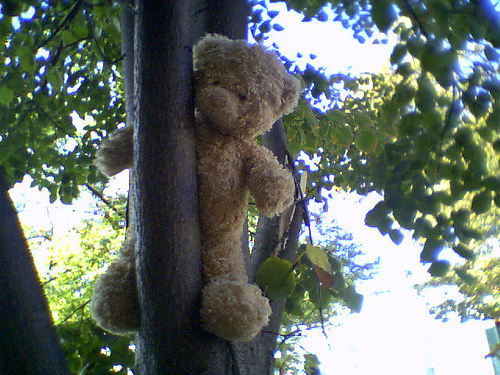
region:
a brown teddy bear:
[91, 29, 298, 339]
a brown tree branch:
[132, 1, 203, 354]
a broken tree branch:
[252, 131, 309, 373]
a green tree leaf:
[252, 255, 295, 300]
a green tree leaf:
[303, 245, 335, 275]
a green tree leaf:
[303, 352, 321, 369]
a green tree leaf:
[385, 227, 405, 243]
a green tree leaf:
[375, 215, 393, 235]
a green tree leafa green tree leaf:
[411, 215, 431, 241]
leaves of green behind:
[351, 85, 492, 264]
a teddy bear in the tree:
[180, 20, 302, 373]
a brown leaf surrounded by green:
[279, 245, 375, 302]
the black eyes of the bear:
[200, 61, 280, 128]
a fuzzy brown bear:
[88, 13, 284, 350]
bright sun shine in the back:
[18, 160, 110, 231]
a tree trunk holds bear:
[124, 51, 209, 325]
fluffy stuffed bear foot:
[202, 278, 267, 345]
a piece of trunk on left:
[10, 213, 45, 358]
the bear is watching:
[156, 16, 313, 238]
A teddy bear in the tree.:
[133, 42, 311, 344]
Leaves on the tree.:
[338, 62, 485, 218]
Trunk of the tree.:
[126, 241, 276, 374]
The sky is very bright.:
[323, 221, 430, 343]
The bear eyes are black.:
[211, 74, 258, 106]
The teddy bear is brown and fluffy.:
[189, 39, 269, 255]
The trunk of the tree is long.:
[119, 2, 213, 359]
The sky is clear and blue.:
[316, 219, 448, 349]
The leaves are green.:
[20, 21, 135, 148]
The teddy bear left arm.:
[253, 138, 298, 214]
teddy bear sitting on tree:
[98, 40, 301, 343]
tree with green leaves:
[1, 0, 498, 370]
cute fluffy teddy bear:
[93, 33, 293, 340]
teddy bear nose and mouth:
[201, 86, 239, 130]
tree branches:
[364, 4, 499, 266]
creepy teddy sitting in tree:
[88, 34, 300, 338]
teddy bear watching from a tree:
[91, 35, 302, 340]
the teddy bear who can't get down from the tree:
[96, 35, 304, 336]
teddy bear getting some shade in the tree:
[93, 35, 299, 340]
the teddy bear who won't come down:
[93, 36, 298, 338]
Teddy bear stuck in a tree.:
[91, 33, 302, 339]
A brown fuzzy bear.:
[93, 33, 302, 335]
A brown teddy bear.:
[92, 35, 304, 341]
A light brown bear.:
[81, 30, 301, 340]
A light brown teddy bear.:
[84, 32, 301, 340]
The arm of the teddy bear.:
[98, 127, 134, 177]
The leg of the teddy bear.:
[91, 225, 136, 339]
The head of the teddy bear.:
[196, 30, 298, 133]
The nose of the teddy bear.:
[207, 90, 228, 111]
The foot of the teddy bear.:
[201, 283, 269, 337]